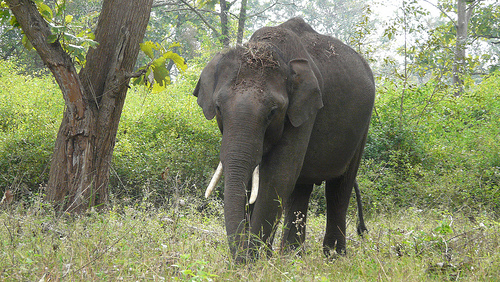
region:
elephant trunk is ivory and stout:
[241, 156, 266, 207]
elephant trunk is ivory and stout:
[204, 152, 229, 202]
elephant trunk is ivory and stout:
[245, 160, 274, 225]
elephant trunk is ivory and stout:
[194, 159, 224, 195]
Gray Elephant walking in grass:
[183, 9, 398, 268]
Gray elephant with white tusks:
[190, 31, 326, 269]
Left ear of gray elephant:
[275, 51, 331, 139]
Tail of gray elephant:
[345, 168, 375, 245]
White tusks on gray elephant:
[201, 155, 263, 207]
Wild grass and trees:
[386, 90, 493, 270]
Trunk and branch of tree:
[1, 1, 184, 217]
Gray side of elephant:
[323, 66, 363, 146]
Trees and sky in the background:
[373, 6, 498, 71]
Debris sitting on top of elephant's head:
[231, 21, 303, 102]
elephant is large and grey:
[160, 12, 416, 264]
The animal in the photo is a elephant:
[182, 5, 404, 277]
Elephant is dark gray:
[175, 8, 426, 276]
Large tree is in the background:
[10, 2, 155, 207]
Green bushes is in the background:
[15, 62, 496, 192]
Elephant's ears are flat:
[185, 43, 325, 143]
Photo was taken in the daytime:
[20, 7, 480, 273]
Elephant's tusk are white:
[197, 155, 280, 215]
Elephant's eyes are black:
[206, 93, 294, 129]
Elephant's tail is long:
[337, 160, 397, 250]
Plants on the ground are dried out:
[15, 209, 200, 274]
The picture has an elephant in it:
[190, 19, 374, 261]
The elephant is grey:
[186, 26, 373, 267]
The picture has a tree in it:
[6, 1, 151, 216]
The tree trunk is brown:
[11, 7, 156, 207]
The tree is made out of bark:
[14, 10, 142, 206]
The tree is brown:
[16, 7, 133, 204]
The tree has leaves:
[138, 42, 175, 104]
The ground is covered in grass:
[37, 205, 233, 262]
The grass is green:
[45, 220, 185, 265]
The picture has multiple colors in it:
[11, 2, 483, 267]